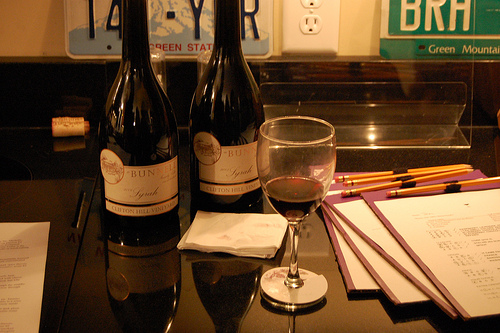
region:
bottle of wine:
[86, 1, 184, 271]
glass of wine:
[249, 111, 355, 321]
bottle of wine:
[187, 4, 276, 217]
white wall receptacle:
[277, 0, 354, 65]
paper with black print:
[385, 206, 495, 289]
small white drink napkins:
[176, 196, 322, 275]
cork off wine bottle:
[32, 98, 98, 149]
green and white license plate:
[365, 1, 498, 66]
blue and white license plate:
[50, 1, 287, 61]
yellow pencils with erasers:
[338, 166, 495, 204]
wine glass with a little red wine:
[252, 98, 355, 325]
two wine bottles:
[84, 0, 269, 275]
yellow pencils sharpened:
[337, 153, 499, 208]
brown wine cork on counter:
[42, 106, 102, 145]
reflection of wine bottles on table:
[111, 216, 256, 327]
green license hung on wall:
[372, 0, 496, 58]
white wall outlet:
[280, 0, 343, 60]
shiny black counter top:
[11, 67, 52, 217]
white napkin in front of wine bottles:
[172, 201, 289, 260]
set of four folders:
[315, 131, 499, 322]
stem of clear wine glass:
[250, 257, 345, 304]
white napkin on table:
[174, 207, 303, 253]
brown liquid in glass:
[251, 171, 361, 213]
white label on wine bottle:
[92, 140, 189, 221]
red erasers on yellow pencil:
[332, 174, 364, 185]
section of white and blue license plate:
[56, 12, 99, 75]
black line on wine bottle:
[104, 191, 192, 216]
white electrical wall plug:
[280, 5, 352, 57]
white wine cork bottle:
[29, 112, 102, 146]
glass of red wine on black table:
[256, 113, 341, 313]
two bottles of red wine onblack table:
[86, 0, 265, 234]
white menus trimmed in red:
[325, 175, 499, 317]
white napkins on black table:
[174, 207, 296, 257]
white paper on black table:
[3, 217, 55, 327]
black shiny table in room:
[0, 55, 498, 316]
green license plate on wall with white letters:
[370, 0, 497, 55]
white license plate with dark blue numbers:
[58, 0, 277, 63]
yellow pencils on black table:
[333, 154, 498, 198]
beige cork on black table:
[50, 110, 93, 142]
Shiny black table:
[48, 198, 169, 332]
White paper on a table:
[9, 218, 81, 331]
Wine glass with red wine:
[241, 105, 393, 324]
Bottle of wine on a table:
[112, 9, 214, 239]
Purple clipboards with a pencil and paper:
[338, 167, 496, 331]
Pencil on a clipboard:
[378, 174, 498, 204]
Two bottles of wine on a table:
[68, 2, 453, 331]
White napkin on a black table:
[178, 188, 317, 308]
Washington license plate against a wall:
[59, 8, 290, 86]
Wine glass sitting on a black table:
[240, 112, 368, 314]